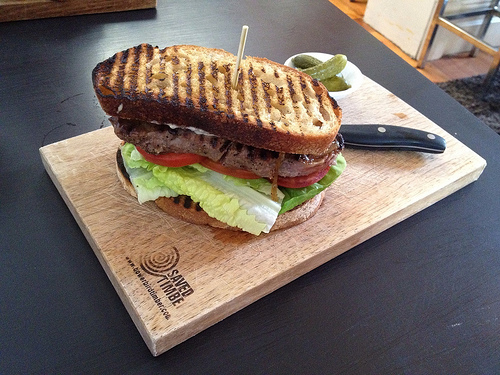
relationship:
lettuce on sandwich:
[125, 144, 282, 234] [88, 43, 348, 236]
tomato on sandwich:
[280, 171, 322, 184] [88, 43, 348, 236]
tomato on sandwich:
[268, 167, 333, 189] [88, 43, 348, 236]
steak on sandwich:
[110, 115, 327, 175] [88, 43, 348, 236]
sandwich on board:
[88, 43, 348, 236] [92, 42, 339, 230]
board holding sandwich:
[38, 56, 488, 358] [88, 43, 348, 236]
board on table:
[38, 56, 488, 358] [2, 4, 496, 373]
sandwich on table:
[88, 43, 348, 236] [2, 4, 496, 373]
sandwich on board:
[88, 43, 348, 236] [38, 56, 488, 358]